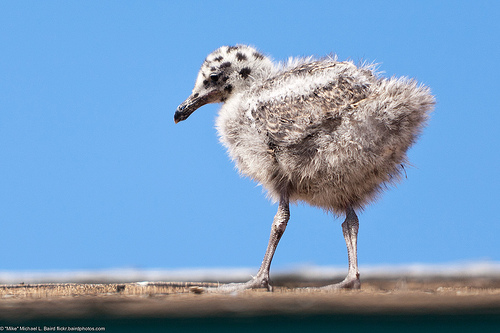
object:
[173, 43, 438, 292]
bird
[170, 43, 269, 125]
head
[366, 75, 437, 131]
tail end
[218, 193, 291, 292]
leg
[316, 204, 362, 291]
leg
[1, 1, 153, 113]
sky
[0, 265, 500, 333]
ground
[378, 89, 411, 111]
fuzz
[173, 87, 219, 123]
beak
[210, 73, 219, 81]
eye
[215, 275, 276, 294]
foot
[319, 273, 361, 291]
foot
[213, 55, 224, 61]
spot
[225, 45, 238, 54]
spot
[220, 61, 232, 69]
spot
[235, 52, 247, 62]
spot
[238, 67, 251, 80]
spot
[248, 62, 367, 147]
wing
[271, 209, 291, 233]
knee